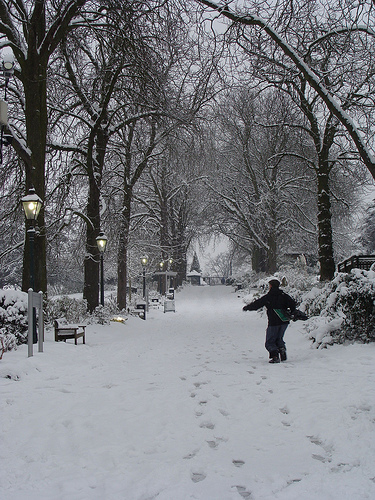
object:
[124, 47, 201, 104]
branch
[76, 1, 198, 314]
tree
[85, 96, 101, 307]
brown oak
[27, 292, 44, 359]
signpost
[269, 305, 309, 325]
snowboard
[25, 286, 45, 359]
banner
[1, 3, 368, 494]
park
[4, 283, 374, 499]
ground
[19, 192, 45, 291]
lamp post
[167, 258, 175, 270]
lamps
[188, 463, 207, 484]
footstep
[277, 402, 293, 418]
footstep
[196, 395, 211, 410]
footstep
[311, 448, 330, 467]
footstep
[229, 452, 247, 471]
footstep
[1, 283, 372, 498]
snow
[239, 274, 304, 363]
guy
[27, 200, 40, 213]
light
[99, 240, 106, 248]
light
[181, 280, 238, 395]
street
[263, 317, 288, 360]
pants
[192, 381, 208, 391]
footprints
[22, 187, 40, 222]
lamp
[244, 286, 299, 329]
coat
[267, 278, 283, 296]
head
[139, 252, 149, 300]
lamp post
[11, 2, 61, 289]
trunk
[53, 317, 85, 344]
bench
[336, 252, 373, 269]
rail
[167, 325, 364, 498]
tracks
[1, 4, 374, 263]
sky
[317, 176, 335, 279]
trunk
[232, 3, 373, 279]
tree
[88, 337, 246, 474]
patch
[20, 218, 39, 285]
post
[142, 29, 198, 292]
tree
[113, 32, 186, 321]
tree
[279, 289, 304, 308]
arm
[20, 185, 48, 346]
street lamps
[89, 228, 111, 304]
street lamps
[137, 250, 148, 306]
street lamps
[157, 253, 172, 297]
street lamps